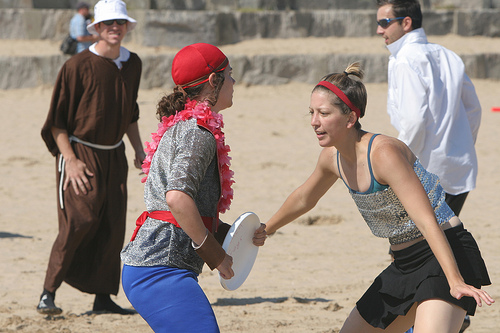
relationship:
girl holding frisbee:
[120, 40, 237, 330] [216, 208, 263, 293]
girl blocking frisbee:
[257, 56, 496, 328] [216, 208, 263, 293]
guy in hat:
[32, 18, 137, 315] [82, 0, 136, 38]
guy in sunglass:
[32, 18, 137, 315] [85, 12, 147, 32]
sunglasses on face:
[377, 17, 405, 28] [370, 4, 406, 42]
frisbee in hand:
[217, 211, 265, 290] [252, 220, 268, 245]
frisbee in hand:
[217, 211, 265, 290] [210, 250, 235, 279]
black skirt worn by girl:
[355, 222, 490, 329] [257, 61, 497, 333]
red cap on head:
[170, 42, 228, 87] [160, 37, 240, 114]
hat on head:
[85, 0, 139, 37] [97, 17, 129, 44]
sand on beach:
[272, 259, 335, 321] [4, 86, 497, 328]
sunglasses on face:
[373, 14, 401, 28] [374, 1, 401, 45]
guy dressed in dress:
[33, 0, 148, 315] [38, 38, 145, 300]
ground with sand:
[25, 98, 499, 332] [272, 252, 339, 325]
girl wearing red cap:
[120, 42, 237, 333] [159, 40, 231, 81]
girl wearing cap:
[257, 61, 497, 333] [169, 40, 232, 87]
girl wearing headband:
[257, 61, 497, 333] [317, 80, 361, 119]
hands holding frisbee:
[240, 206, 285, 257] [220, 212, 259, 291]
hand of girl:
[430, 257, 498, 315] [257, 61, 497, 333]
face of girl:
[308, 83, 348, 147] [257, 61, 497, 333]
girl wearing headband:
[257, 56, 496, 328] [312, 77, 364, 119]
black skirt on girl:
[355, 222, 492, 329] [257, 61, 497, 333]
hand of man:
[46, 143, 116, 196] [42, 5, 144, 317]